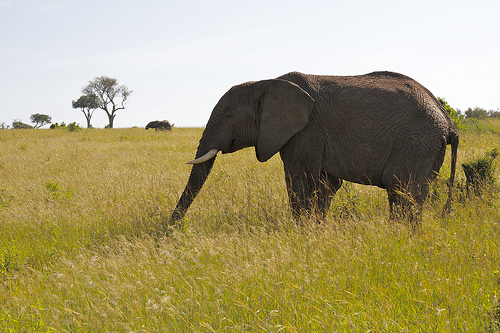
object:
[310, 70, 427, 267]
field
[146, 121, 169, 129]
animal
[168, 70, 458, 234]
animal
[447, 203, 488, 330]
grass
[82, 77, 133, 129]
trees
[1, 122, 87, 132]
bushes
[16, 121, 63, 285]
field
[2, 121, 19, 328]
grass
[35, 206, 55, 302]
grass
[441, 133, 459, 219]
tail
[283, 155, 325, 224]
leg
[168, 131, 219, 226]
trunk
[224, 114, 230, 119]
eye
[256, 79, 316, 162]
ear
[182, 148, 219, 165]
tusk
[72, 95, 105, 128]
trees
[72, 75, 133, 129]
side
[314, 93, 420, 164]
tough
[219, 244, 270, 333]
ground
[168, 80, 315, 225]
head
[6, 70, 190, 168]
light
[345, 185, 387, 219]
grass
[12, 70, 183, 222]
horizon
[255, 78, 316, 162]
large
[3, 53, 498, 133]
sky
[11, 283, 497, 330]
field